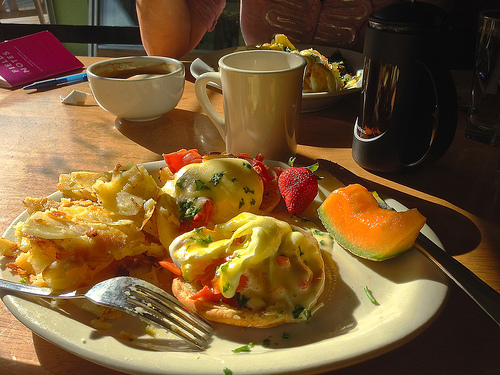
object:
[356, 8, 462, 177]
cup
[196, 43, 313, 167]
cup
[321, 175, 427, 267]
cantaloupe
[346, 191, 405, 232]
bite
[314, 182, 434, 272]
slice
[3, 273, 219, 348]
fork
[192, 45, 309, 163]
mug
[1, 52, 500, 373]
table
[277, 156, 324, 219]
strawberry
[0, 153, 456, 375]
plate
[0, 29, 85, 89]
book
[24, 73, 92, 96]
pen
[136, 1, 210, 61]
elbow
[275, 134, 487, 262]
shadow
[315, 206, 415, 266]
rind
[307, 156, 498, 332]
knife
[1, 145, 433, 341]
breakfast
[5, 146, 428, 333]
food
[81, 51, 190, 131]
cup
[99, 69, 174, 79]
coffee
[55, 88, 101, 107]
paper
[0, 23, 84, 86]
notebook